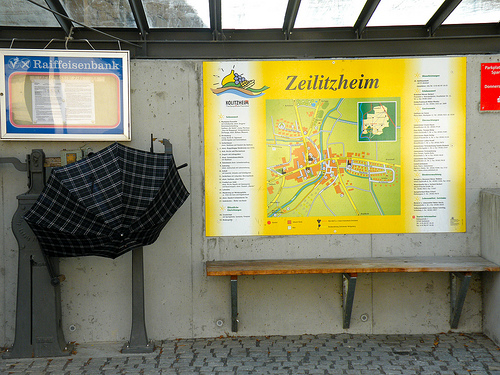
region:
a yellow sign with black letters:
[186, 39, 487, 245]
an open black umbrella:
[28, 154, 195, 282]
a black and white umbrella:
[23, 129, 233, 307]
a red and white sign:
[474, 46, 498, 116]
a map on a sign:
[261, 85, 422, 243]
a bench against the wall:
[196, 220, 498, 363]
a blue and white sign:
[8, 37, 153, 147]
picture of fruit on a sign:
[213, 67, 261, 99]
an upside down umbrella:
[36, 127, 239, 329]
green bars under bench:
[219, 287, 487, 352]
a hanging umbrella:
[21, 128, 192, 273]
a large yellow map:
[198, 51, 475, 251]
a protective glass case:
[2, 40, 150, 169]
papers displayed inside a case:
[22, 75, 100, 131]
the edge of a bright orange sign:
[472, 55, 498, 105]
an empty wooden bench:
[192, 246, 499, 303]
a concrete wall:
[7, 42, 497, 346]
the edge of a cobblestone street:
[12, 350, 469, 371]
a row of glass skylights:
[26, 2, 468, 41]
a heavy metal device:
[4, 152, 79, 358]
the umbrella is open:
[0, 98, 194, 268]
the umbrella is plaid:
[17, 142, 189, 260]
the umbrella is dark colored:
[2, 107, 190, 296]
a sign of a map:
[233, 80, 420, 242]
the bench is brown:
[180, 238, 495, 308]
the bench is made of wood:
[184, 236, 491, 297]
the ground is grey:
[198, 324, 467, 369]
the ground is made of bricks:
[200, 325, 412, 367]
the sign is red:
[475, 55, 497, 115]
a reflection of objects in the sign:
[7, 51, 122, 133]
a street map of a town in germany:
[201, 53, 471, 234]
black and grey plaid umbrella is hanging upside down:
[19, 140, 191, 265]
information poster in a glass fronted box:
[1, 48, 132, 145]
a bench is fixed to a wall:
[206, 250, 498, 340]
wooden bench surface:
[206, 251, 499, 281]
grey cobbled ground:
[2, 327, 497, 374]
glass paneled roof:
[2, 1, 499, 42]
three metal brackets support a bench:
[213, 273, 482, 334]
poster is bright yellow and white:
[200, 55, 468, 237]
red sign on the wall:
[478, 59, 498, 114]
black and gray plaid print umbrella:
[12, 132, 192, 277]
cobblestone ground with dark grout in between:
[183, 336, 325, 373]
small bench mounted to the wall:
[192, 252, 495, 339]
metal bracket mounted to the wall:
[326, 270, 371, 328]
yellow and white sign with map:
[198, 57, 473, 238]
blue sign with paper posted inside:
[0, 48, 139, 142]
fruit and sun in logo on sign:
[207, 62, 272, 104]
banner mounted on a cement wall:
[180, 61, 245, 242]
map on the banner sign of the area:
[264, 101, 401, 217]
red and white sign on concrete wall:
[473, 59, 499, 119]